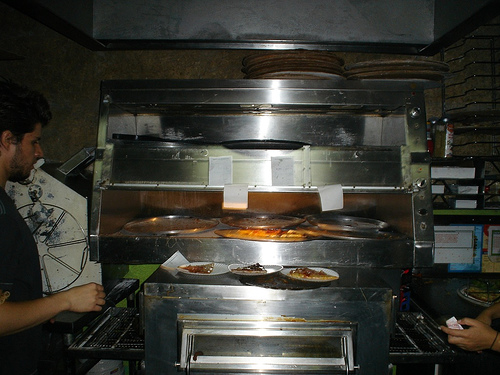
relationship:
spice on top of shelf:
[164, 127, 178, 140] [103, 104, 409, 149]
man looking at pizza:
[0, 79, 105, 374] [212, 226, 321, 244]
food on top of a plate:
[183, 262, 215, 276] [176, 260, 233, 278]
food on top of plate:
[231, 261, 267, 275] [228, 261, 285, 280]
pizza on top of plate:
[290, 265, 337, 282] [277, 265, 341, 284]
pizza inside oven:
[212, 226, 321, 244] [55, 81, 435, 298]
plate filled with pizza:
[277, 265, 341, 284] [290, 265, 337, 282]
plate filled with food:
[176, 260, 233, 278] [183, 262, 215, 276]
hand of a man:
[69, 282, 106, 313] [0, 79, 105, 374]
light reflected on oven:
[256, 83, 287, 195] [55, 81, 435, 298]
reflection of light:
[245, 78, 289, 374] [256, 83, 287, 195]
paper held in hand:
[5, 160, 104, 298] [69, 282, 106, 313]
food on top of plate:
[183, 262, 215, 276] [176, 260, 233, 278]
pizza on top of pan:
[223, 212, 302, 228] [213, 212, 306, 231]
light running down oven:
[256, 83, 287, 195] [55, 81, 435, 298]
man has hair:
[0, 79, 105, 374] [0, 81, 51, 142]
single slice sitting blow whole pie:
[290, 265, 337, 282] [223, 212, 302, 228]